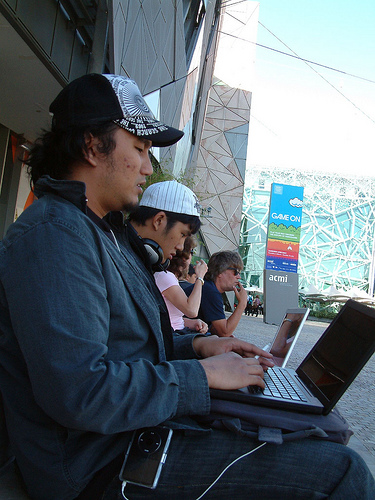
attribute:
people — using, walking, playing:
[30, 112, 343, 445]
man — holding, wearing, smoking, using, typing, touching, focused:
[153, 249, 225, 316]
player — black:
[157, 293, 215, 337]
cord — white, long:
[170, 440, 260, 488]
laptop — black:
[289, 326, 347, 391]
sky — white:
[268, 60, 331, 119]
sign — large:
[257, 174, 311, 283]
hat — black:
[29, 74, 197, 135]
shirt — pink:
[158, 257, 197, 331]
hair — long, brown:
[179, 231, 204, 270]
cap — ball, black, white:
[62, 63, 191, 124]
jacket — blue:
[201, 290, 240, 337]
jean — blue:
[241, 436, 325, 499]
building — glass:
[180, 24, 210, 58]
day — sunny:
[243, 35, 342, 158]